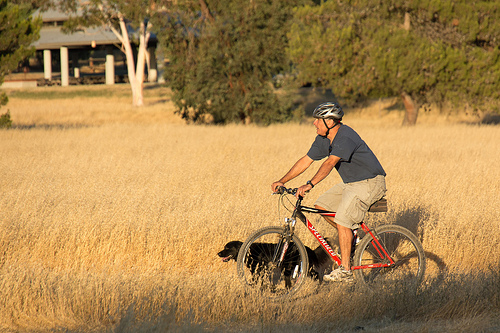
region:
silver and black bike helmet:
[309, 100, 344, 122]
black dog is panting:
[215, 236, 302, 281]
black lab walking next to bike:
[215, 237, 320, 295]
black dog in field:
[206, 234, 339, 302]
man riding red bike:
[240, 75, 440, 303]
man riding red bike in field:
[217, 94, 417, 296]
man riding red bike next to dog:
[210, 90, 421, 330]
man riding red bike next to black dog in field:
[215, 82, 420, 312]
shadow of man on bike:
[362, 202, 432, 281]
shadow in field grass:
[128, 288, 495, 323]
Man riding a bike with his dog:
[213, 100, 426, 299]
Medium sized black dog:
[216, 233, 333, 291]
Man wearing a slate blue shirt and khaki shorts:
[270, 99, 390, 282]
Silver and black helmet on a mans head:
[312, 98, 344, 138]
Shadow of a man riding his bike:
[260, 202, 449, 306]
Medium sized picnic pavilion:
[30, 23, 162, 84]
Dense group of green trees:
[159, 0, 497, 127]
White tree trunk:
[100, 6, 161, 105]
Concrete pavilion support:
[57, 44, 71, 86]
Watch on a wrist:
[304, 176, 314, 191]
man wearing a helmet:
[288, 96, 373, 155]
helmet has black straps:
[308, 113, 348, 142]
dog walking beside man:
[198, 231, 363, 309]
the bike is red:
[262, 201, 382, 256]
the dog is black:
[206, 226, 335, 280]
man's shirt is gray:
[294, 140, 436, 187]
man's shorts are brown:
[320, 169, 416, 229]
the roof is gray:
[28, 11, 157, 46]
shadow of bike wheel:
[398, 248, 458, 285]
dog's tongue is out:
[206, 235, 252, 274]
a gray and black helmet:
[312, 100, 342, 135]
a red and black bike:
[236, 183, 426, 295]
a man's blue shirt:
[306, 128, 395, 180]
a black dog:
[213, 238, 310, 271]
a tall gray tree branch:
[112, 15, 157, 102]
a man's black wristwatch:
[305, 176, 315, 190]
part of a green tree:
[367, 26, 497, 117]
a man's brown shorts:
[315, 174, 389, 227]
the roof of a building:
[20, 25, 121, 45]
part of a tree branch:
[401, 94, 421, 126]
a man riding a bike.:
[224, 80, 431, 312]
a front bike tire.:
[227, 222, 321, 299]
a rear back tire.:
[340, 223, 434, 298]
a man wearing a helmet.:
[305, 75, 360, 155]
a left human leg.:
[306, 219, 352, 291]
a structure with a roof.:
[30, 23, 175, 104]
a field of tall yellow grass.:
[2, 99, 497, 326]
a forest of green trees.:
[156, 0, 496, 145]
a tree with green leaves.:
[48, 0, 164, 110]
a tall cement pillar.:
[58, 42, 71, 92]